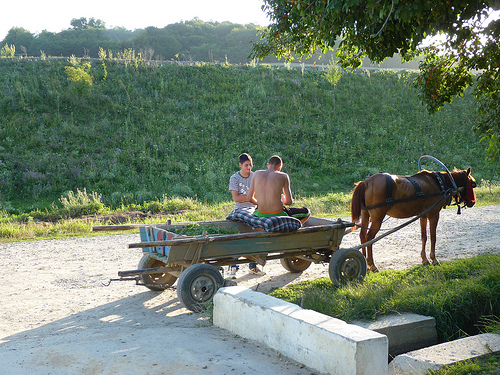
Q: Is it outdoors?
A: Yes, it is outdoors.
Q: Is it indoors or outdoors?
A: It is outdoors.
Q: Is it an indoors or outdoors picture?
A: It is outdoors.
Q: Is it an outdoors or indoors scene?
A: It is outdoors.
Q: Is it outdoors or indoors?
A: It is outdoors.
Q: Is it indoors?
A: No, it is outdoors.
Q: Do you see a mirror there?
A: No, there are no mirrors.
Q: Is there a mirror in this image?
A: No, there are no mirrors.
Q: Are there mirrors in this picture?
A: No, there are no mirrors.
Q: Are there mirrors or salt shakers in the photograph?
A: No, there are no mirrors or salt shakers.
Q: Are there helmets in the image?
A: No, there are no helmets.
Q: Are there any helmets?
A: No, there are no helmets.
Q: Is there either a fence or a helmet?
A: No, there are no helmets or fences.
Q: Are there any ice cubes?
A: No, there are no ice cubes.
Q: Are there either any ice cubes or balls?
A: No, there are no ice cubes or balls.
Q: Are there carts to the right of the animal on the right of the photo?
A: No, the cart is to the left of the horse.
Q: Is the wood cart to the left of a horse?
A: Yes, the cart is to the left of a horse.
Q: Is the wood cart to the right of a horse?
A: No, the cart is to the left of a horse.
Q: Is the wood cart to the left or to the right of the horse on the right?
A: The cart is to the left of the horse.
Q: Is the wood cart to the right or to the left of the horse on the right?
A: The cart is to the left of the horse.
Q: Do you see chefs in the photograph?
A: No, there are no chefs.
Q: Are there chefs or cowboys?
A: No, there are no chefs or cowboys.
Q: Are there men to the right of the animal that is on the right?
A: No, the man is to the left of the horse.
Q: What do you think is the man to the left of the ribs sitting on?
A: The man is sitting on the cart.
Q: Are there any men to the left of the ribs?
A: Yes, there is a man to the left of the ribs.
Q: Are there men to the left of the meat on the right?
A: Yes, there is a man to the left of the ribs.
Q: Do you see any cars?
A: No, there are no cars.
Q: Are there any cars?
A: No, there are no cars.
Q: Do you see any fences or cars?
A: No, there are no cars or fences.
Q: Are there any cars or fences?
A: No, there are no cars or fences.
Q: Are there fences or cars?
A: No, there are no cars or fences.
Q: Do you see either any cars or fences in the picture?
A: No, there are no cars or fences.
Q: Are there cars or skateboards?
A: No, there are no cars or skateboards.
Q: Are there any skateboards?
A: No, there are no skateboards.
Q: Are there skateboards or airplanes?
A: No, there are no skateboards or airplanes.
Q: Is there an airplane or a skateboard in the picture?
A: No, there are no skateboards or airplanes.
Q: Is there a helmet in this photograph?
A: No, there are no helmets.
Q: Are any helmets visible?
A: No, there are no helmets.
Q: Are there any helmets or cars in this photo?
A: No, there are no helmets or cars.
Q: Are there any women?
A: No, there are no women.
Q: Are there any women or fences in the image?
A: No, there are no women or fences.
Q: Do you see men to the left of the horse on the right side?
A: Yes, there are men to the left of the horse.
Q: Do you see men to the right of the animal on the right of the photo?
A: No, the men are to the left of the horse.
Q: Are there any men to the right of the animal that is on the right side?
A: No, the men are to the left of the horse.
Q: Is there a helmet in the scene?
A: No, there are no helmets.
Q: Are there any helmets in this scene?
A: No, there are no helmets.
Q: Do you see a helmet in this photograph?
A: No, there are no helmets.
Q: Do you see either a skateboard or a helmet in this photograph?
A: No, there are no helmets or skateboards.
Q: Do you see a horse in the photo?
A: Yes, there is a horse.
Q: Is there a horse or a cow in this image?
A: Yes, there is a horse.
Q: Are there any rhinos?
A: No, there are no rhinos.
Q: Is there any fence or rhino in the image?
A: No, there are no rhinos or fences.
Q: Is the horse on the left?
A: No, the horse is on the right of the image.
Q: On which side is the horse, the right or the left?
A: The horse is on the right of the image.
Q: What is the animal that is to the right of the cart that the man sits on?
A: The animal is a horse.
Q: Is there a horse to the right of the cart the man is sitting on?
A: Yes, there is a horse to the right of the cart.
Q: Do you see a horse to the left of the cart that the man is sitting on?
A: No, the horse is to the right of the cart.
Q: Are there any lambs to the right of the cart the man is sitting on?
A: No, there is a horse to the right of the cart.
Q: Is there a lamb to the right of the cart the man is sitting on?
A: No, there is a horse to the right of the cart.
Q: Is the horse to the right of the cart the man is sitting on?
A: Yes, the horse is to the right of the cart.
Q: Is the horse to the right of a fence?
A: No, the horse is to the right of the cart.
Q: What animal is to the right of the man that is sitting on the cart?
A: The animal is a horse.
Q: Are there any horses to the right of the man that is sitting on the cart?
A: Yes, there is a horse to the right of the man.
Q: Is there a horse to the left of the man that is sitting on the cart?
A: No, the horse is to the right of the man.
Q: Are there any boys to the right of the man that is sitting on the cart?
A: No, there is a horse to the right of the man.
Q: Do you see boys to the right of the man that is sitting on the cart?
A: No, there is a horse to the right of the man.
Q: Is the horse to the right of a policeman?
A: No, the horse is to the right of a man.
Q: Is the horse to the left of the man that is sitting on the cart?
A: No, the horse is to the right of the man.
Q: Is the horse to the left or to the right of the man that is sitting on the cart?
A: The horse is to the right of the man.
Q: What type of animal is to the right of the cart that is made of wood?
A: The animal is a horse.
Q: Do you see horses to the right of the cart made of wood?
A: Yes, there is a horse to the right of the cart.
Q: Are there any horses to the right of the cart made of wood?
A: Yes, there is a horse to the right of the cart.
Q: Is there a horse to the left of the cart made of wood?
A: No, the horse is to the right of the cart.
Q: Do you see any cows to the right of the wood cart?
A: No, there is a horse to the right of the cart.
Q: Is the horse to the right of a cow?
A: No, the horse is to the right of the cart.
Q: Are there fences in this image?
A: No, there are no fences.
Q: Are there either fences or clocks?
A: No, there are no fences or clocks.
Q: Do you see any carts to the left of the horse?
A: Yes, there is a cart to the left of the horse.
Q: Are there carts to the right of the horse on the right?
A: No, the cart is to the left of the horse.